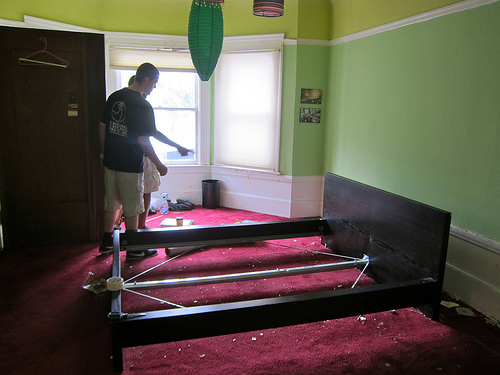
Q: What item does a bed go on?
A: Bed frame.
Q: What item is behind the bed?
A: A wall.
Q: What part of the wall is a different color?
A: Top part.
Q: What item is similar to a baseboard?
A: The molding.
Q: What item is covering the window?
A: Window shade.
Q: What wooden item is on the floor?
A: Bed frame.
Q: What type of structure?
A: Light fixture.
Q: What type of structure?
A: Window.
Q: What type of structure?
A: Bed.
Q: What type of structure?
A: Window.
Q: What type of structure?
A: Window.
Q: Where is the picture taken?
A: A bedroom.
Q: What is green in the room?
A: The walls.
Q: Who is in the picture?
A: Two men.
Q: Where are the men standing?
A: On the carpet.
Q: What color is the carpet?
A: Red.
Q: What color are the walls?
A: Green and yellow.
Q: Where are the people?
A: On the carpet.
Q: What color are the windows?
A: White.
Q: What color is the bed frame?
A: Brown.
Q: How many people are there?
A: Two.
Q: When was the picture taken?
A: Daytime.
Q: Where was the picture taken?
A: In the bedroom.